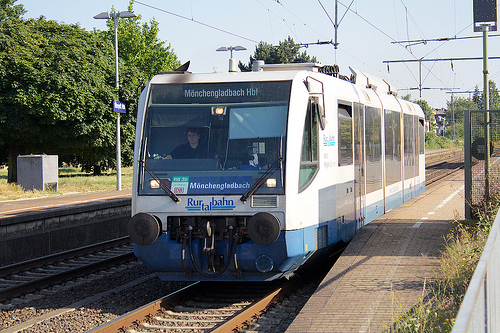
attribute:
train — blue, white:
[119, 40, 451, 272]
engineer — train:
[169, 121, 209, 166]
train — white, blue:
[121, 72, 427, 291]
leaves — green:
[61, 87, 66, 92]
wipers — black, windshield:
[138, 158, 183, 211]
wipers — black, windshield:
[236, 154, 282, 198]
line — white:
[359, 160, 495, 329]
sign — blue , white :
[96, 78, 156, 132]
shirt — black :
[158, 110, 210, 157]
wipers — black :
[145, 109, 305, 230]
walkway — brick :
[287, 153, 487, 331]